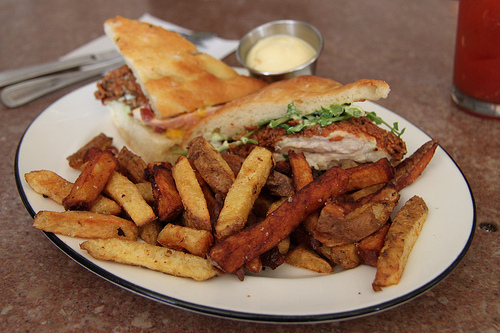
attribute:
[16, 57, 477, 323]
plate — white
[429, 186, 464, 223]
plate — white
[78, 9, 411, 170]
sandwich — chicken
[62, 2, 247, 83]
napkin — white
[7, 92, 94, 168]
plate — white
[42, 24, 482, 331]
plate — white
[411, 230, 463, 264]
plate — white